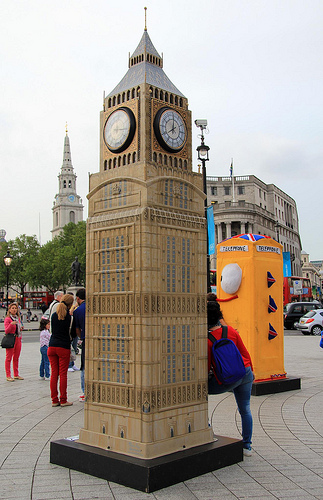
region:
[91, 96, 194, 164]
Two clocks on a tower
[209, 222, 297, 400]
A telephone booth with a face on it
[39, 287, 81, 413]
A woman in red pants with a pony tail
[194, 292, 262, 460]
A person with a blue backpack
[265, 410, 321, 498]
Curved tiles on the ground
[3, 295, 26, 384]
A woman in red with a black bag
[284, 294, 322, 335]
Two cars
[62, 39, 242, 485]
A miniature Big Ben clock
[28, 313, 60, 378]
A little girl in a pink shirt and jeans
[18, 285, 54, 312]
A double decker bus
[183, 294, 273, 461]
woman leaning on building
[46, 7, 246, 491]
there is a grand clock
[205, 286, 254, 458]
a girl standing by the clock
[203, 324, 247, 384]
the girl has a blue and black back pack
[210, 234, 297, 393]
look like porter bath room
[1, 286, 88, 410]
there are some people standing on the side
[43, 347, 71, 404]
lady wearing red pants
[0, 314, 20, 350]
lady caring black bag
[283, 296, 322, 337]
two park on the side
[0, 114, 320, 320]
gray building in the back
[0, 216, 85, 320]
there are trees and light pole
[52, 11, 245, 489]
A decorative clock tower.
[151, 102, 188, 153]
A round clock face on the right side.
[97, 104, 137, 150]
A round clock face on the left side.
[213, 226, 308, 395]
A yellow telephone booth.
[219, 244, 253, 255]
The word TELEPHONE in black letters.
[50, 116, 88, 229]
A large steeple in the background.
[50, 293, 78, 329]
A woman with long blonde hair.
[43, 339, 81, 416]
A woman with her back to camera wearing red pants.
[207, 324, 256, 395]
A blue backpack.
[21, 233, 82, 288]
Green trees in the background.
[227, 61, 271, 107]
part of the sky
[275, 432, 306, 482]
part of the floor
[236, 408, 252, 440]
part of trouser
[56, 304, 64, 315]
hair of a lady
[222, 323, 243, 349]
part of a red sweater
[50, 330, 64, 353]
part of a black top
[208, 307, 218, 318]
part of a marvin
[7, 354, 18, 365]
part of a pink trouser